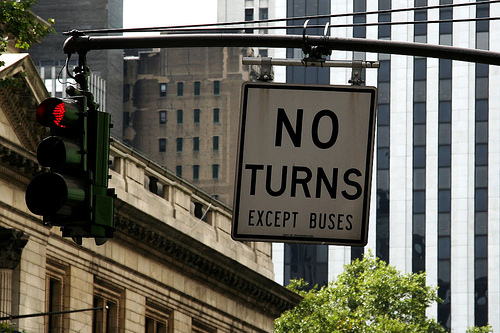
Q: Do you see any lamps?
A: No, there are no lamps.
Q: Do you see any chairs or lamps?
A: No, there are no lamps or chairs.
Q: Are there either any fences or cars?
A: No, there are no cars or fences.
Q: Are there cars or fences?
A: No, there are no cars or fences.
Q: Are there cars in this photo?
A: No, there are no cars.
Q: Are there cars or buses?
A: No, there are no cars or buses.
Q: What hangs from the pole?
A: The sign hangs from the pole.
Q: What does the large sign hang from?
A: The sign hangs from the pole.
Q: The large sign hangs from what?
A: The sign hangs from the pole.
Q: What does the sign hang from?
A: The sign hangs from the pole.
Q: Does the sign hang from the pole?
A: Yes, the sign hangs from the pole.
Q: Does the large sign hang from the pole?
A: Yes, the sign hangs from the pole.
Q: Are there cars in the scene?
A: No, there are no cars.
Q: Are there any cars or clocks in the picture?
A: No, there are no cars or clocks.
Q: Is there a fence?
A: No, there are no fences.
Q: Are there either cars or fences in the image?
A: No, there are no fences or cars.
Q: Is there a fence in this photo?
A: No, there are no fences.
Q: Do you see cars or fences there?
A: No, there are no fences or cars.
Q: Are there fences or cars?
A: No, there are no fences or cars.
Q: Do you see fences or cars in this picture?
A: No, there are no fences or cars.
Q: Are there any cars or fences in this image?
A: No, there are no fences or cars.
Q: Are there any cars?
A: No, there are no cars.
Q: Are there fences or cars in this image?
A: No, there are no cars or fences.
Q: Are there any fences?
A: No, there are no fences.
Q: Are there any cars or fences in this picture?
A: No, there are no fences or cars.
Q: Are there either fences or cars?
A: No, there are no fences or cars.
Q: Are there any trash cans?
A: No, there are no trash cans.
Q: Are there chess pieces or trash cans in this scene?
A: No, there are no trash cans or chess pieces.